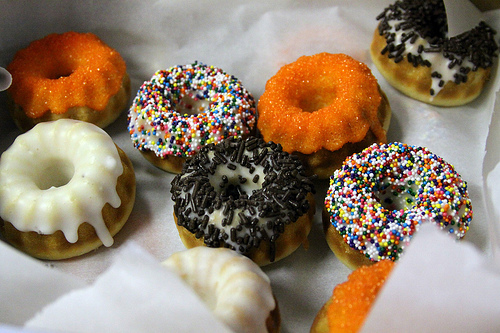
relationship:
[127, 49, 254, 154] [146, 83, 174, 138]
donut with confetti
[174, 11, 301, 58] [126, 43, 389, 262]
paper under donuts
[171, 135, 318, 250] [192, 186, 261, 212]
donut covered with chocolate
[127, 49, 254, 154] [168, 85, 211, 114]
donut with center hole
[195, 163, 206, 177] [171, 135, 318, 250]
part of a donut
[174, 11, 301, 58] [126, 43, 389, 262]
paper covering donuts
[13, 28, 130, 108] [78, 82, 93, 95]
doughnut with orange frosting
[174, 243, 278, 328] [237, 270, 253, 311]
doughnut with white frosting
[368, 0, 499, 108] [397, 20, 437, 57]
doughnut with chocolate sprinkles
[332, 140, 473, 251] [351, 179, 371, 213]
doughnut with rainbow sprinkles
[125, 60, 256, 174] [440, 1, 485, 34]
donut on white paper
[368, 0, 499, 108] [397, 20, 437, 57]
doughnut under chocolate sprinkles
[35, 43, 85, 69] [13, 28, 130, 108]
orange icing over doughnut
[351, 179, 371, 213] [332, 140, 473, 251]
sprinkles on top of doughnut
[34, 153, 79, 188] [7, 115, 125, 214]
hole in doughnut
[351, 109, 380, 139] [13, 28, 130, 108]
ridges on doughnut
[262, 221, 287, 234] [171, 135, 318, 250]
edge of a doughnut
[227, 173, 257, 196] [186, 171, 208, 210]
hole covered with black sprinkles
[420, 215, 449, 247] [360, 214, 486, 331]
edge of white paper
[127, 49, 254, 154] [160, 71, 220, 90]
donut covered with sprinkles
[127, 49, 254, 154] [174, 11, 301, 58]
donut on paper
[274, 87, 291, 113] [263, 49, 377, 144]
frosting on a donut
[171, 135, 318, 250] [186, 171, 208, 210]
donut in black sprinkles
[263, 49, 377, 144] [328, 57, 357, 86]
donut with orange toppings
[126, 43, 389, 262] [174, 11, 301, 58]
donuts on paper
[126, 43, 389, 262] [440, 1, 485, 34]
donuts on white paper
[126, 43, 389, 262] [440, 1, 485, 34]
donuts on a white paper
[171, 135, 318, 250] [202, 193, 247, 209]
donut with dark sprinkles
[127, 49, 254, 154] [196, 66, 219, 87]
donut with colorful sprinkles